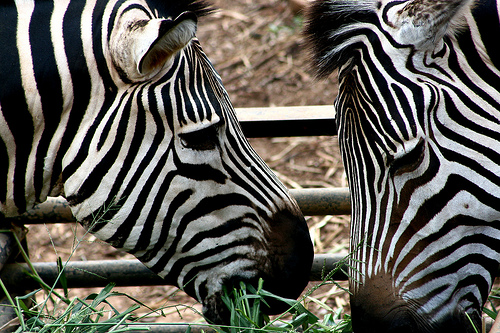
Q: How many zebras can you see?
A: Two.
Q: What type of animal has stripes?
A: Zebras.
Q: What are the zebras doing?
A: Eating grass.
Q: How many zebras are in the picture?
A: 2.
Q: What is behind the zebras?
A: Wooden fence.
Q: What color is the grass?
A: Green.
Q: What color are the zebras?
A: Black and white.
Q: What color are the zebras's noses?
A: Black-brown.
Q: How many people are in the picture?
A: None.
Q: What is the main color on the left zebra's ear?
A: White.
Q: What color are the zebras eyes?
A: Black.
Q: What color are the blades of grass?
A: Green.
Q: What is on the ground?
A: Dirt and hay.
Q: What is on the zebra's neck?
A: Stripes.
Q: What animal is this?
A: Zebra.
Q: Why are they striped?
A: Camoflage.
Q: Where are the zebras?
A: Inside a fence.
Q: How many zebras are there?
A: Two.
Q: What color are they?
A: Black and white and brown.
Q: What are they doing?
A: Eating grass.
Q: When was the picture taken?
A: During the day.